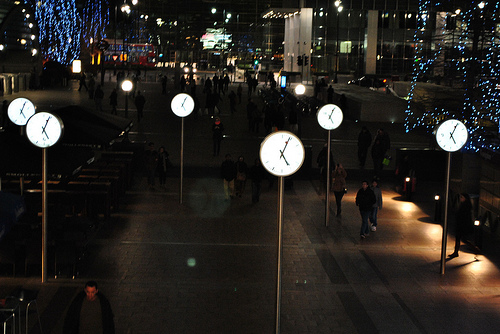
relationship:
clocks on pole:
[6, 96, 39, 131] [16, 124, 28, 201]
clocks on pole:
[22, 111, 66, 155] [38, 146, 47, 288]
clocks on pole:
[168, 90, 196, 121] [176, 117, 187, 204]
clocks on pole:
[254, 129, 306, 182] [270, 175, 284, 332]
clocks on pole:
[312, 101, 345, 136] [325, 131, 335, 237]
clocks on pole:
[433, 116, 469, 159] [440, 150, 454, 279]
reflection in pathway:
[184, 173, 235, 222] [26, 155, 429, 333]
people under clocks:
[327, 160, 352, 219] [312, 101, 345, 136]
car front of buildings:
[342, 71, 389, 92] [259, 3, 484, 98]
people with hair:
[350, 179, 380, 242] [359, 180, 370, 189]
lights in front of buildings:
[293, 52, 312, 69] [259, 3, 484, 98]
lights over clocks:
[397, 2, 499, 155] [433, 116, 469, 159]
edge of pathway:
[278, 175, 378, 333] [26, 155, 429, 333]